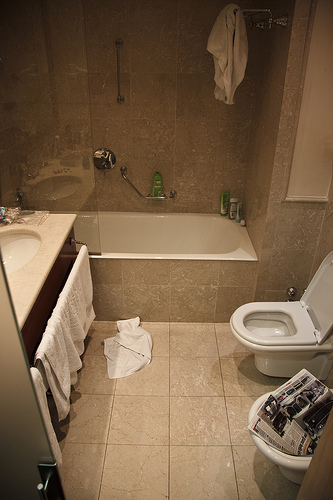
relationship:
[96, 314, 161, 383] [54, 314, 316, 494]
towel on floor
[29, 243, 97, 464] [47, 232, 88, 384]
towel hanging on bar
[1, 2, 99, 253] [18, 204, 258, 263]
glass surrounds tub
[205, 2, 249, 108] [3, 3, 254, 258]
towel in shower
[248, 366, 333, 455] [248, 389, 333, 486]
magazines in basin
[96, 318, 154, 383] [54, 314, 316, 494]
towel laying on floor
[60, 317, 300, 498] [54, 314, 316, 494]
floor on floor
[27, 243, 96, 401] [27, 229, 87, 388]
rod hanging on rod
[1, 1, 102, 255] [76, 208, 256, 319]
glass door on tub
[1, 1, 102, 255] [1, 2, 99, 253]
glass door in glass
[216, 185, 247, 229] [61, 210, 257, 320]
products in corner of tub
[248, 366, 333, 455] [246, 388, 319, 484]
magazines in basin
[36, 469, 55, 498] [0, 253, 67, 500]
handle on bathroom door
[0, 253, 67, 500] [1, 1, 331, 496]
bathroom door to bathroom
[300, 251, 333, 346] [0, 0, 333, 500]
lid to bathroom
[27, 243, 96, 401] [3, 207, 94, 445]
rod hanging on front of vanity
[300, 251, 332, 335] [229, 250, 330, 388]
lid of toilet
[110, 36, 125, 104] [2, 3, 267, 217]
handle on shower wall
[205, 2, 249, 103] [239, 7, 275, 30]
towel hanging on shower head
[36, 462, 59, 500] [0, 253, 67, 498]
handle on bathroom door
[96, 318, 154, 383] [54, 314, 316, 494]
towel on floor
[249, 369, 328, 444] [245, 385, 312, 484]
magazines in basket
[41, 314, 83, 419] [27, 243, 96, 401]
towel hanging on rod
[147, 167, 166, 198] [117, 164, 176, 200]
green bottle sitting on rail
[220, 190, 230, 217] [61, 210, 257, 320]
green bottle sitting on tub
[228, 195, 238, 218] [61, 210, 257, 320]
soap sitting on tub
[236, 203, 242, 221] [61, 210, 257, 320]
soap sitting on tub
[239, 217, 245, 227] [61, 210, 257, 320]
soap sitting on tub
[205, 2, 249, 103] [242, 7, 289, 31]
towel hanging on shower head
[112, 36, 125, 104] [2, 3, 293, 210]
handle attached to shower wall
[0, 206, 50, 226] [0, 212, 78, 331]
bag sitting on counter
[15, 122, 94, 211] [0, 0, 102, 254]
sink reflected in shower door